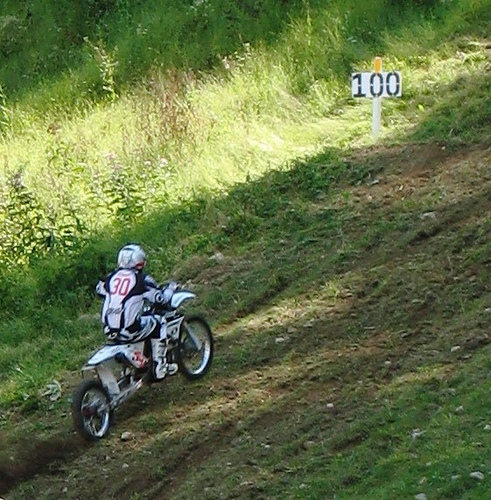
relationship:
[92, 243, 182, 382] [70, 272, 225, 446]
person riding dirtbike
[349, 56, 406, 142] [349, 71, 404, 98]
sign marking 100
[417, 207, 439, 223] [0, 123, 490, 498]
stones on field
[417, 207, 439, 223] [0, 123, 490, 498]
stones in field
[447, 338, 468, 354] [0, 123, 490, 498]
stones on field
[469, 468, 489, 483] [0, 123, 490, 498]
stones on field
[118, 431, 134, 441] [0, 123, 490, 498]
stones in field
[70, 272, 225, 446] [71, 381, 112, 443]
dirtbike riding on tires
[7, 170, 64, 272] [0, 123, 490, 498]
plants growing in field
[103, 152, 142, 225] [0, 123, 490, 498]
plants growing in field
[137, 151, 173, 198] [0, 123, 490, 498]
plants growing in field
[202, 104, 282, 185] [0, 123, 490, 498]
plants growing in field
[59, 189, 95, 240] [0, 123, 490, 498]
plants growing in field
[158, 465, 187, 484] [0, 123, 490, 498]
dirt on field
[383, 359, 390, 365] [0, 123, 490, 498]
rocks on field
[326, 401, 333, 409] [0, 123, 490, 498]
dirt on field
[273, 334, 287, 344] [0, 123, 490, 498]
rocks on field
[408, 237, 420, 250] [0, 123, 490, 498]
dirt on field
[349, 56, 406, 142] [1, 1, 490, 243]
sign standing in field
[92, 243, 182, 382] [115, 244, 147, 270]
person wearing helmet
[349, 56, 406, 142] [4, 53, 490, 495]
number marker on track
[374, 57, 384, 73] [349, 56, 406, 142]
yellow tip of sign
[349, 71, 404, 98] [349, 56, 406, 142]
number 100 written on white wood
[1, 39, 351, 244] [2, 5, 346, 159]
sunshine rays on grass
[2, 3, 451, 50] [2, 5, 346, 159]
shadows on grass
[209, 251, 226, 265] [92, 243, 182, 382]
rocks in front of rider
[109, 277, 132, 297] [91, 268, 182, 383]
number 30 written on outfit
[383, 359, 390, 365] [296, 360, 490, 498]
rocks on grass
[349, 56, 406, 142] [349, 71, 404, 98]
sign with black numbers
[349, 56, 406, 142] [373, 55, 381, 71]
sign with yellow reflector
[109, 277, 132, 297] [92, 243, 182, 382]
number 30 written on person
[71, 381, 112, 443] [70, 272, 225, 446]
rear wheel riding on dirtbike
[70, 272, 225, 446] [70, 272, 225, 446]
dirtbike of dirtbike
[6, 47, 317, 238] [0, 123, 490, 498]
tall weeds in field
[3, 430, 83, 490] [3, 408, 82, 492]
dirt in air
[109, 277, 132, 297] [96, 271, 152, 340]
numbers written on person's back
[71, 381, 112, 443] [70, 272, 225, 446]
back wheel of dirtbike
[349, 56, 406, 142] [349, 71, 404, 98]
sign marking distance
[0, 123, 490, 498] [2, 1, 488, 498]
tack up hill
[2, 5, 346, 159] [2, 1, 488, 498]
grass on hill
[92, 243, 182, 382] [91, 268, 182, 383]
person wearing outfit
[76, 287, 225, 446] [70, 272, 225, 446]
dirtbike has dirtbike